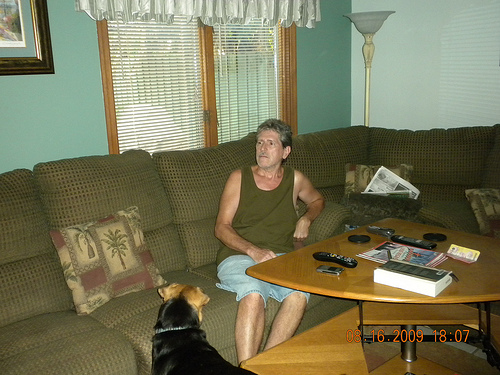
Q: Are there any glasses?
A: No, there are no glasses.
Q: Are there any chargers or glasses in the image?
A: No, there are no glasses or chargers.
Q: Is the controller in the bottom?
A: Yes, the controller is in the bottom of the image.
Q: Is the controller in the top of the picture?
A: No, the controller is in the bottom of the image.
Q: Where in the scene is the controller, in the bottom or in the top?
A: The controller is in the bottom of the image.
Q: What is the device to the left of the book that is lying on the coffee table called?
A: The device is a controller.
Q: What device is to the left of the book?
A: The device is a controller.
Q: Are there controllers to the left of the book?
A: Yes, there is a controller to the left of the book.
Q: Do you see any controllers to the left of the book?
A: Yes, there is a controller to the left of the book.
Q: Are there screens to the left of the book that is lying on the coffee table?
A: No, there is a controller to the left of the book.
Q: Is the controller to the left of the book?
A: Yes, the controller is to the left of the book.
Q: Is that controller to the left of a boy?
A: No, the controller is to the left of the book.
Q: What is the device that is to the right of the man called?
A: The device is a controller.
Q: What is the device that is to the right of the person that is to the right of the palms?
A: The device is a controller.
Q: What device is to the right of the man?
A: The device is a controller.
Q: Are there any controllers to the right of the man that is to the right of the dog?
A: Yes, there is a controller to the right of the man.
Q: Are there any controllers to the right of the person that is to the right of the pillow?
A: Yes, there is a controller to the right of the man.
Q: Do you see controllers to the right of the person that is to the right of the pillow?
A: Yes, there is a controller to the right of the man.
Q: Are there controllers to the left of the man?
A: No, the controller is to the right of the man.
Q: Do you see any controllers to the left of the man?
A: No, the controller is to the right of the man.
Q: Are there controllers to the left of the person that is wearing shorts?
A: No, the controller is to the right of the man.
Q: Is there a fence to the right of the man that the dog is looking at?
A: No, there is a controller to the right of the man.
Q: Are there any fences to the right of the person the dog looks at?
A: No, there is a controller to the right of the man.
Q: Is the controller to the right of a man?
A: Yes, the controller is to the right of a man.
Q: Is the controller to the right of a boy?
A: No, the controller is to the right of a man.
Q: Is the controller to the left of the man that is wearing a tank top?
A: No, the controller is to the right of the man.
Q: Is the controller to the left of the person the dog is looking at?
A: No, the controller is to the right of the man.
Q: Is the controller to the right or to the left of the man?
A: The controller is to the right of the man.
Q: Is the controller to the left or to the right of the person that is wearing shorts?
A: The controller is to the right of the man.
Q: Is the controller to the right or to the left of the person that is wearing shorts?
A: The controller is to the right of the man.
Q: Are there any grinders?
A: No, there are no grinders.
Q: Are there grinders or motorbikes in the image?
A: No, there are no grinders or motorbikes.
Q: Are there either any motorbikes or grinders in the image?
A: No, there are no grinders or motorbikes.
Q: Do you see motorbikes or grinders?
A: No, there are no grinders or motorbikes.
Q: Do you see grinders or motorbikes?
A: No, there are no grinders or motorbikes.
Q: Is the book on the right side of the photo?
A: Yes, the book is on the right of the image.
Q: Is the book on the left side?
A: No, the book is on the right of the image.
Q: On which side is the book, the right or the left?
A: The book is on the right of the image.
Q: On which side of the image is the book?
A: The book is on the right of the image.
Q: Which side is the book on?
A: The book is on the right of the image.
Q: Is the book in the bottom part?
A: Yes, the book is in the bottom of the image.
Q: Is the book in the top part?
A: No, the book is in the bottom of the image.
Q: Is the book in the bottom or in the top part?
A: The book is in the bottom of the image.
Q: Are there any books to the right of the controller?
A: Yes, there is a book to the right of the controller.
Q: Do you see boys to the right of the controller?
A: No, there is a book to the right of the controller.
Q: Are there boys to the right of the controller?
A: No, there is a book to the right of the controller.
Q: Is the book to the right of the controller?
A: Yes, the book is to the right of the controller.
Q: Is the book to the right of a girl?
A: No, the book is to the right of the controller.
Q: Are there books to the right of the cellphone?
A: Yes, there is a book to the right of the cellphone.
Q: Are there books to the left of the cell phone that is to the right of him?
A: No, the book is to the right of the cell phone.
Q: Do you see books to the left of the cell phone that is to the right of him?
A: No, the book is to the right of the cell phone.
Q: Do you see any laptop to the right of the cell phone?
A: No, there is a book to the right of the cell phone.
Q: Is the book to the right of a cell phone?
A: Yes, the book is to the right of a cell phone.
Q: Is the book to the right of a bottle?
A: No, the book is to the right of a cell phone.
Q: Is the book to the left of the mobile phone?
A: No, the book is to the right of the mobile phone.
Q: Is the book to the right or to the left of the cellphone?
A: The book is to the right of the cellphone.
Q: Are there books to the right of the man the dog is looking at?
A: Yes, there is a book to the right of the man.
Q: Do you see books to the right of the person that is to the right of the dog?
A: Yes, there is a book to the right of the man.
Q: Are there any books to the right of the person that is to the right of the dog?
A: Yes, there is a book to the right of the man.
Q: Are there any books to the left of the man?
A: No, the book is to the right of the man.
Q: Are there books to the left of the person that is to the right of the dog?
A: No, the book is to the right of the man.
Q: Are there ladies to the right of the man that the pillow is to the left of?
A: No, there is a book to the right of the man.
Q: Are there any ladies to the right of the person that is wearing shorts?
A: No, there is a book to the right of the man.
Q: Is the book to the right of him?
A: Yes, the book is to the right of the man.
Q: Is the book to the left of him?
A: No, the book is to the right of the man.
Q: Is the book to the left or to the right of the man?
A: The book is to the right of the man.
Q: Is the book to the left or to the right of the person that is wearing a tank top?
A: The book is to the right of the man.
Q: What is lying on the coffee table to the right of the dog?
A: The book is lying on the coffee table.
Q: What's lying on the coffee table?
A: The book is lying on the coffee table.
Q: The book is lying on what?
A: The book is lying on the coffee table.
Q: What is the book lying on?
A: The book is lying on the coffee table.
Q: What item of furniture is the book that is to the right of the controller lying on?
A: The book is lying on the coffee table.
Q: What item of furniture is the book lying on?
A: The book is lying on the coffee table.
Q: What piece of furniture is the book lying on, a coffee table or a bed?
A: The book is lying on a coffee table.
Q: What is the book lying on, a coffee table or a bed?
A: The book is lying on a coffee table.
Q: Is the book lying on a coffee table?
A: Yes, the book is lying on a coffee table.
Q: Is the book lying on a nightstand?
A: No, the book is lying on a coffee table.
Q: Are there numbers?
A: Yes, there are numbers.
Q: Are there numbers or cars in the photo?
A: Yes, there are numbers.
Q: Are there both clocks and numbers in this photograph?
A: No, there are numbers but no clocks.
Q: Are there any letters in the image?
A: No, there are no letters.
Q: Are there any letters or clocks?
A: No, there are no letters or clocks.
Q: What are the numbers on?
A: The numbers are on the picture.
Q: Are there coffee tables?
A: Yes, there is a coffee table.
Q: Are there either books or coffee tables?
A: Yes, there is a coffee table.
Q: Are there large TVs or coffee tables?
A: Yes, there is a large coffee table.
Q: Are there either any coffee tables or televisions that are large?
A: Yes, the coffee table is large.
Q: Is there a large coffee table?
A: Yes, there is a large coffee table.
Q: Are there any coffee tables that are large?
A: Yes, there is a coffee table that is large.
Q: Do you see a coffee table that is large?
A: Yes, there is a coffee table that is large.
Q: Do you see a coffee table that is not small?
A: Yes, there is a large coffee table.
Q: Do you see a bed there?
A: No, there are no beds.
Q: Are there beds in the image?
A: No, there are no beds.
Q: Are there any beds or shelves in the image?
A: No, there are no beds or shelves.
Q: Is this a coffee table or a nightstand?
A: This is a coffee table.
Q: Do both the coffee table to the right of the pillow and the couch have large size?
A: Yes, both the coffee table and the couch are large.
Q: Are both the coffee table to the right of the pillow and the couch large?
A: Yes, both the coffee table and the couch are large.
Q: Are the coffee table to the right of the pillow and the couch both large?
A: Yes, both the coffee table and the couch are large.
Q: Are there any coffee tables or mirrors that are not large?
A: No, there is a coffee table but it is large.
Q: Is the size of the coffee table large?
A: Yes, the coffee table is large.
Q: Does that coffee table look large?
A: Yes, the coffee table is large.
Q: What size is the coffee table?
A: The coffee table is large.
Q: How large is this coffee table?
A: The coffee table is large.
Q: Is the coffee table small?
A: No, the coffee table is large.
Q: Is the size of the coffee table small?
A: No, the coffee table is large.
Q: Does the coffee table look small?
A: No, the coffee table is large.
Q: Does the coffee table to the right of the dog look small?
A: No, the coffee table is large.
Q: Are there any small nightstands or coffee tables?
A: No, there is a coffee table but it is large.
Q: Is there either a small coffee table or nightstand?
A: No, there is a coffee table but it is large.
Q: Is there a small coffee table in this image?
A: No, there is a coffee table but it is large.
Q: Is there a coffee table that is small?
A: No, there is a coffee table but it is large.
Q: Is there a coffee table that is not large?
A: No, there is a coffee table but it is large.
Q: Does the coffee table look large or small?
A: The coffee table is large.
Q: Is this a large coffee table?
A: Yes, this is a large coffee table.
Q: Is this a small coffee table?
A: No, this is a large coffee table.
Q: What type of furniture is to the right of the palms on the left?
A: The piece of furniture is a coffee table.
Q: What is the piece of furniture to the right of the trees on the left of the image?
A: The piece of furniture is a coffee table.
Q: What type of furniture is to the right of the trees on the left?
A: The piece of furniture is a coffee table.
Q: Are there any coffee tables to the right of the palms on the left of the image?
A: Yes, there is a coffee table to the right of the palms.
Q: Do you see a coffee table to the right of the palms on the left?
A: Yes, there is a coffee table to the right of the palms.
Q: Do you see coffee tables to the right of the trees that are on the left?
A: Yes, there is a coffee table to the right of the palms.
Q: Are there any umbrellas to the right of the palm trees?
A: No, there is a coffee table to the right of the palm trees.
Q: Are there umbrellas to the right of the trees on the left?
A: No, there is a coffee table to the right of the palm trees.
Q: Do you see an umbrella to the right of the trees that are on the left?
A: No, there is a coffee table to the right of the palm trees.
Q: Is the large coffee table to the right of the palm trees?
A: Yes, the coffee table is to the right of the palm trees.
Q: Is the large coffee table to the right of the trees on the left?
A: Yes, the coffee table is to the right of the palm trees.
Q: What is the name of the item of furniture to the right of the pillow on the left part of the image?
A: The piece of furniture is a coffee table.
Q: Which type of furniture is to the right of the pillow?
A: The piece of furniture is a coffee table.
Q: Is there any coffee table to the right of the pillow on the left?
A: Yes, there is a coffee table to the right of the pillow.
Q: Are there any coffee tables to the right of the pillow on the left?
A: Yes, there is a coffee table to the right of the pillow.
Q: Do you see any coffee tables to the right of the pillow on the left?
A: Yes, there is a coffee table to the right of the pillow.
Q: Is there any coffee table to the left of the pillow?
A: No, the coffee table is to the right of the pillow.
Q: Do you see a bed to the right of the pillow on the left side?
A: No, there is a coffee table to the right of the pillow.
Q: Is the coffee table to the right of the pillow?
A: Yes, the coffee table is to the right of the pillow.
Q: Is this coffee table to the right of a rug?
A: No, the coffee table is to the right of the pillow.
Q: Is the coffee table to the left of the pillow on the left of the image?
A: No, the coffee table is to the right of the pillow.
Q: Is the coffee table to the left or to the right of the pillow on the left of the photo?
A: The coffee table is to the right of the pillow.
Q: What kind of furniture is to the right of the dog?
A: The piece of furniture is a coffee table.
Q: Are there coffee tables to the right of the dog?
A: Yes, there is a coffee table to the right of the dog.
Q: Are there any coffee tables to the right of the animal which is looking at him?
A: Yes, there is a coffee table to the right of the dog.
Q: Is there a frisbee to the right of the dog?
A: No, there is a coffee table to the right of the dog.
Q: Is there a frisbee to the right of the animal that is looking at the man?
A: No, there is a coffee table to the right of the dog.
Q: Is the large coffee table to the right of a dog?
A: Yes, the coffee table is to the right of a dog.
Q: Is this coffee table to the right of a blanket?
A: No, the coffee table is to the right of a dog.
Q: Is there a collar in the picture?
A: Yes, there is a collar.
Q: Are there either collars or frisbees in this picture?
A: Yes, there is a collar.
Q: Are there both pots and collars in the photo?
A: No, there is a collar but no pots.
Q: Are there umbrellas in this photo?
A: No, there are no umbrellas.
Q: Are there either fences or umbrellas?
A: No, there are no umbrellas or fences.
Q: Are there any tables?
A: Yes, there is a table.